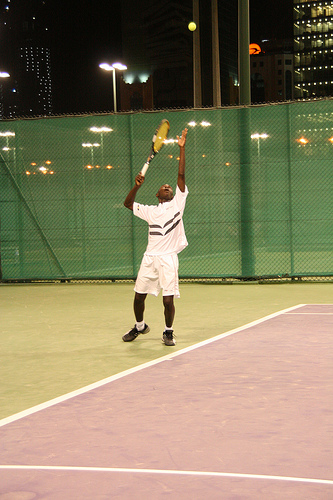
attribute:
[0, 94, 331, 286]
fence — green, mesh, behind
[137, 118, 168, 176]
racket — black, yellow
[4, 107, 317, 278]
net — green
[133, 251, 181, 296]
shorts — white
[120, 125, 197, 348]
man — hitting, serving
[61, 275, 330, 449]
tennis court — pink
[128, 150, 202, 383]
man — playing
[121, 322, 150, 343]
shoe — black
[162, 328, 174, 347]
shoe — black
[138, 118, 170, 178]
racket — white, yellow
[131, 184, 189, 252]
shirt — white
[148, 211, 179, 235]
stripes — black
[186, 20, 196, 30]
ball — yellow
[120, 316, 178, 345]
shoes — black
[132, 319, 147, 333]
socks — short, white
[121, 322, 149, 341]
shoes — gray, black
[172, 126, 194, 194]
arm — stretching, upward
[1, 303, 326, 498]
court — red, clay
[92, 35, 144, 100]
light — above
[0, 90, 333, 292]
netting — green 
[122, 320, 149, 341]
athletic shoe — laced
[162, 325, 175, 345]
athletic shoe — laced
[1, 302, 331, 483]
lines — white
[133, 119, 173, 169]
racket — tennis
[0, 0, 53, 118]
building — lit up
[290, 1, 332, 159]
building lights — tall